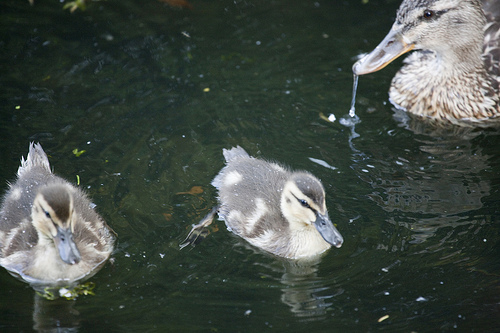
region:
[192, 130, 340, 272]
small duck in the water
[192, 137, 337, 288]
small duck in a lake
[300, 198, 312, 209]
small black eye of duck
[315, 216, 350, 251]
grey beak of duck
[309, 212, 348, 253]
grey bill of duck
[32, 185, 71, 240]
brown and tan head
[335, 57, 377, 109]
water dripping down beak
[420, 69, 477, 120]
feathers on side of duck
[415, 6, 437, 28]
black and brown eye of duck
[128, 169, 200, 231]
leaves floating in water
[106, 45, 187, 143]
the water is murky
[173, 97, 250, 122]
the water is murky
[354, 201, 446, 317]
the water is murky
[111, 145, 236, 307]
the water is murky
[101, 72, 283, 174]
the water is murky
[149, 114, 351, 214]
the water is dirty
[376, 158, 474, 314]
the water is dirty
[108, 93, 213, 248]
the water is dirty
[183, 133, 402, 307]
a duck on the water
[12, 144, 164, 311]
a duck on the water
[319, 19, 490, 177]
a duck on the water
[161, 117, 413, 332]
the duck is brown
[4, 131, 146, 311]
the duck is brown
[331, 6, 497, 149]
the duck is brown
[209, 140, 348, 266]
There are ducks in the water.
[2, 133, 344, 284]
There are two baby ducks.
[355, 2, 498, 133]
There is a mother duck.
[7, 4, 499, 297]
There are three ducks.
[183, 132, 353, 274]
The baby duck is swimming.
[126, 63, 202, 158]
The water is green.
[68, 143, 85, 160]
There are leaves in the water.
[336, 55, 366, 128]
There is water on the mother duck's nose.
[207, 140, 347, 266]
The ducks are yellow and brown.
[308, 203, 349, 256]
The ducks have black noses.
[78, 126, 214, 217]
Leaves in the water.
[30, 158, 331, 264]
Two little ducks in the water.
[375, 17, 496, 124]
The duck is drinking water.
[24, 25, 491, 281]
Three ducks in the pond.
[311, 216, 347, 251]
The duck beak is black.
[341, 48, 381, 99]
Water coming from the duck beak.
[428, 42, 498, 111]
The duck is brown and white.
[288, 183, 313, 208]
The duck right eye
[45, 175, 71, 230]
The top of the duck head is black.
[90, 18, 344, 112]
The water is very dark.